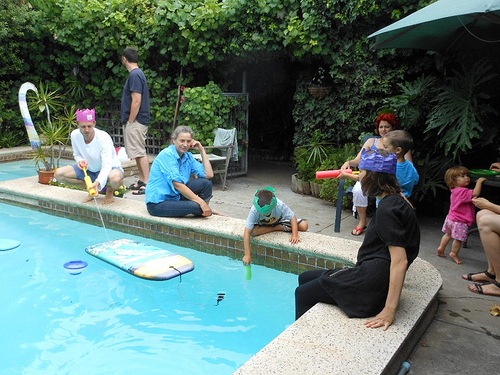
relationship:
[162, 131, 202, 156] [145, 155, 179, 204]
man wearing shirt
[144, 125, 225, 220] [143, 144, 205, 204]
man wearing shirt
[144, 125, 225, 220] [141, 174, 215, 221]
man wearing pants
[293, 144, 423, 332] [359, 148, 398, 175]
man wearing crown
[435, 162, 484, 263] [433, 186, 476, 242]
toddler wearing outfit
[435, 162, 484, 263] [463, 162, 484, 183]
toddler hanging on to table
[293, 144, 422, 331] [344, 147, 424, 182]
man wearing hat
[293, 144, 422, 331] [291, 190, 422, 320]
man wearing outfit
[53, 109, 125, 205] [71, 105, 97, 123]
man wearing paper hat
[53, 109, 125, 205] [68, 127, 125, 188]
man wearing outfit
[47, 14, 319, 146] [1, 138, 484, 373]
foliage growing near pool area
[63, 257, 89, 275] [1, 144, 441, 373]
device floating in pool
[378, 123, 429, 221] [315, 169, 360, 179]
boy holding object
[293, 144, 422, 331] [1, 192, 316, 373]
man sitting by pool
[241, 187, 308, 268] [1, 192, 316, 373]
boy sitting by pool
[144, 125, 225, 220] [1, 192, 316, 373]
man sitting by pool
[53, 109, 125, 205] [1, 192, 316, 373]
man sitting by pool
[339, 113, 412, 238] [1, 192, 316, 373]
person sitting by pool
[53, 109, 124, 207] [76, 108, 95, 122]
man wearing paper hat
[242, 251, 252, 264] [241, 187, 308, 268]
hand belonging to boy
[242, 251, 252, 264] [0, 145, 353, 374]
hand hanging in pool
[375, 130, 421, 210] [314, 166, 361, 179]
boy holding object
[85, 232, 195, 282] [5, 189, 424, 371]
object floating in pool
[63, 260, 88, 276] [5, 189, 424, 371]
device floating in pool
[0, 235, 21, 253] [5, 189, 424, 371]
object floating in pool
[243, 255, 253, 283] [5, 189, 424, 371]
object floating in pool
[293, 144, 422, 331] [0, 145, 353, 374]
man sitting by pool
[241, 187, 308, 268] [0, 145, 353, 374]
boy sitting by pool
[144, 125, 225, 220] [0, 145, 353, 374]
man sitting by pool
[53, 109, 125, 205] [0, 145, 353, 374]
man sitting by pool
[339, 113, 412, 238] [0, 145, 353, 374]
person sitting by pool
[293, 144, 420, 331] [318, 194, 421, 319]
woman wearing outfit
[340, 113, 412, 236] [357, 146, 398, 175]
person wearing crown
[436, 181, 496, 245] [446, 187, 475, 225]
girl wearing outfit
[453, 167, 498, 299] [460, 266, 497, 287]
woman wearing sandal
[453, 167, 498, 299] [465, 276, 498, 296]
woman wearing sandal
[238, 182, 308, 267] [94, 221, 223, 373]
boy touching water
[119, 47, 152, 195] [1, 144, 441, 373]
man sitting on pool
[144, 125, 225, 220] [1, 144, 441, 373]
man sitting on pool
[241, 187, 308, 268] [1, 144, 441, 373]
boy sitting on pool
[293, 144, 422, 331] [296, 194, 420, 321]
man dressed in black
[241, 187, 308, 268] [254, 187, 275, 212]
boy wearing crown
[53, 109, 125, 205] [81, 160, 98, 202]
man squirting gun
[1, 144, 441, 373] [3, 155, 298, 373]
pool filled with water